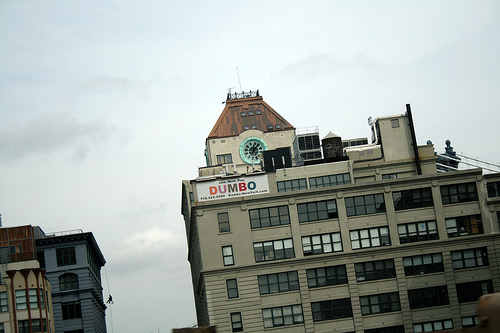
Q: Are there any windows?
A: Yes, there is a window.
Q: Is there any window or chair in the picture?
A: Yes, there is a window.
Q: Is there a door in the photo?
A: No, there are no doors.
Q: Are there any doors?
A: No, there are no doors.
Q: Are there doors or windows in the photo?
A: Yes, there is a window.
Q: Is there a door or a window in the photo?
A: Yes, there is a window.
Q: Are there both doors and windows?
A: No, there is a window but no doors.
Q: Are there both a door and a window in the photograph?
A: No, there is a window but no doors.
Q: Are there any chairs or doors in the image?
A: No, there are no doors or chairs.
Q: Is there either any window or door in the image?
A: Yes, there is a window.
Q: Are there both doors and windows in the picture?
A: No, there is a window but no doors.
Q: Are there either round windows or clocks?
A: Yes, there is a round window.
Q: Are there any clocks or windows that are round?
A: Yes, the window is round.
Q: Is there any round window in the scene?
A: Yes, there is a round window.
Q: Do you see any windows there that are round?
A: Yes, there is a window that is round.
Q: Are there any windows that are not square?
A: Yes, there is a round window.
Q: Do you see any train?
A: No, there are no trains.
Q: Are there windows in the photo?
A: Yes, there is a window.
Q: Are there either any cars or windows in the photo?
A: Yes, there is a window.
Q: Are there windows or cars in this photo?
A: Yes, there is a window.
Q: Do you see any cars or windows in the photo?
A: Yes, there is a window.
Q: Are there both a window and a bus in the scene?
A: No, there is a window but no buses.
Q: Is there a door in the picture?
A: No, there are no doors.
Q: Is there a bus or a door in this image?
A: No, there are no doors or buses.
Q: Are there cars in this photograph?
A: No, there are no cars.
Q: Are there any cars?
A: No, there are no cars.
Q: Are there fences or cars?
A: No, there are no cars or fences.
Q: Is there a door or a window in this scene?
A: Yes, there is a window.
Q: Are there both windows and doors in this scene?
A: No, there is a window but no doors.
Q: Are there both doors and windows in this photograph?
A: No, there is a window but no doors.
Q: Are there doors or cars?
A: No, there are no cars or doors.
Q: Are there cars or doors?
A: No, there are no cars or doors.